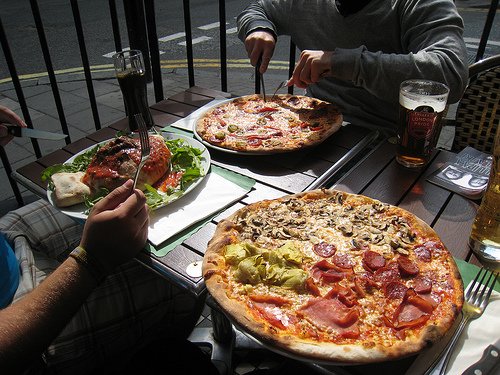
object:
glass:
[395, 78, 450, 170]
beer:
[396, 99, 446, 165]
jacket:
[237, 0, 468, 131]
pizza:
[196, 92, 345, 156]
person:
[2, 105, 154, 375]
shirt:
[0, 235, 21, 309]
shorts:
[1, 195, 198, 375]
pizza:
[203, 189, 466, 365]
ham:
[303, 294, 366, 332]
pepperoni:
[312, 239, 356, 264]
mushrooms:
[298, 230, 311, 240]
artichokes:
[223, 241, 306, 291]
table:
[9, 83, 500, 375]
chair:
[432, 52, 499, 155]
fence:
[0, 0, 499, 156]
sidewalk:
[2, 30, 201, 213]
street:
[2, 0, 499, 88]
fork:
[269, 70, 332, 102]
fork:
[129, 111, 151, 198]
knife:
[256, 58, 267, 101]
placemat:
[148, 167, 259, 258]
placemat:
[454, 254, 499, 299]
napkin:
[148, 171, 252, 247]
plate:
[46, 131, 212, 222]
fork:
[424, 266, 497, 372]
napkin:
[404, 277, 499, 373]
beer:
[118, 69, 152, 130]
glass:
[112, 50, 154, 132]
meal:
[47, 132, 173, 206]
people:
[229, 0, 470, 130]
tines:
[273, 89, 279, 98]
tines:
[141, 113, 150, 148]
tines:
[465, 266, 483, 302]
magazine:
[425, 145, 493, 197]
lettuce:
[172, 150, 188, 163]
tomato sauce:
[164, 178, 171, 185]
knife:
[3, 125, 69, 140]